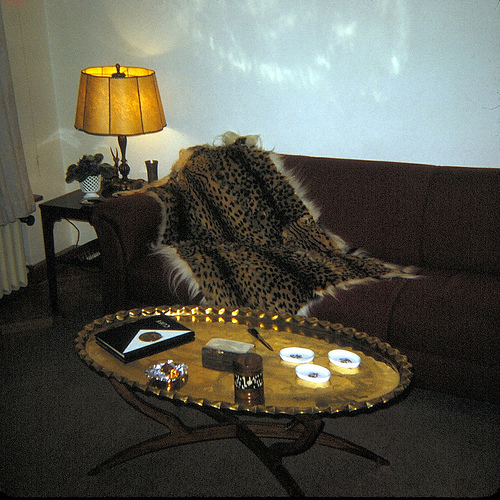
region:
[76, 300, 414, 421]
a oval coffee table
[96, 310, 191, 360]
black and white books on table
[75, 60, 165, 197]
a light on a stand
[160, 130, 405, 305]
a fur on a couch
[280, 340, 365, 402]
small white bowls on a table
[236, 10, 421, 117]
reflection on a wall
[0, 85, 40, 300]
curtains at a window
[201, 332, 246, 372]
a small box on the table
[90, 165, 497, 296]
a brown couch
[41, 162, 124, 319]
a end stand in the corner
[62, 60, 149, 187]
lamp on the table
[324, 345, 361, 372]
dish on the coffee table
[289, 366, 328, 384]
dish on the coffee table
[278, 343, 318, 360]
dish on the coffee table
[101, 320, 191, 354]
book on the coffee table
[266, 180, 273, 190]
leopard spot on blanket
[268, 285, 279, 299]
leopard spot on blanket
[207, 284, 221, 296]
leopard spot on blanket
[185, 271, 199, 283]
leopard spot on blanket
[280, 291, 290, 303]
leopard spot on blanket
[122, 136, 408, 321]
a leopard rug on a couch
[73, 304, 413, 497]
a golden oval table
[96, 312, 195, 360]
a book on a table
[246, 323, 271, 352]
a pen on a table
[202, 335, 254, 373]
a small gray box on a table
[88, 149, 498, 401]
a brown couch in a living room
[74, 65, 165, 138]
a yellow lampshade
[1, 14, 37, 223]
white drapes on a window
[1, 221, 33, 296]
a white radiator against the wall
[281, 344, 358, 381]
three small plates on a table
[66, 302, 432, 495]
A coffee table in a living room.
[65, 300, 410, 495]
A table with various items on top.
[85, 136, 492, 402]
A dark brown couch in a living room.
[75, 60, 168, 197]
A lampshade on the side of a couch.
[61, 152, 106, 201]
A plant on a white flower vase.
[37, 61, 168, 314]
A stool with lampshade on top.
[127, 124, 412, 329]
A shawl on a couch.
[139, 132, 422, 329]
An animal printed shawl on top of a couch.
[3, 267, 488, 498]
Floor with a dark colored carpet.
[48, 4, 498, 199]
A grey colored wall of a living room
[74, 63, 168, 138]
lamp with yellow shade with light on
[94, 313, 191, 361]
black book on golden metal table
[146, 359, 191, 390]
candy bowl on golden table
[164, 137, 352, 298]
leopard skin blanket on sofa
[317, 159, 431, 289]
brown couch with blanket on it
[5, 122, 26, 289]
white and grey curtains on window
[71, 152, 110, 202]
white flower pot on wooden table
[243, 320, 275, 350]
silver and black letter opener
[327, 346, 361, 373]
white coaster on gold table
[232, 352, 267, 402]
tin can on gold table